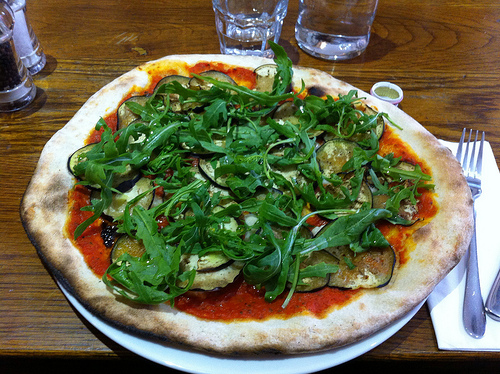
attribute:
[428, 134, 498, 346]
napkin — folded, white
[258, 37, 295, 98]
spinach — small, leafy, green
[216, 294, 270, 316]
sauce — orange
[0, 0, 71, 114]
shakers — Salt , pepper 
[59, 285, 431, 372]
white plate — round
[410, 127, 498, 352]
napkin — folded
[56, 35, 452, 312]
dandelion greens — dandelion 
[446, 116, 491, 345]
fork — laying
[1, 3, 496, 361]
table — wood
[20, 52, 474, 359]
crust — well cooked, brown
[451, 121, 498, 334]
fork — stainless steel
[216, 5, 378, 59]
glasses — empty, clear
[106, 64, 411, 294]
vegetable — green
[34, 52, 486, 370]
pizza crust — black 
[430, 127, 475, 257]
crust — burned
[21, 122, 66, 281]
crust — burned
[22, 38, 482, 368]
pizza — vegetarian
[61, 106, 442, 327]
vegetables — green 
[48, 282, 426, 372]
plate — white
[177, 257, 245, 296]
eggplant — Sliced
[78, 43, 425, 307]
vegetables — leafy 